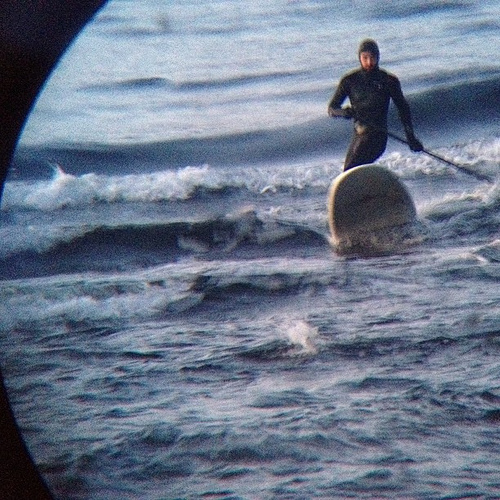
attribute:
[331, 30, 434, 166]
wet suit — black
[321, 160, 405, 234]
board — white, whtie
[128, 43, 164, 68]
water — blue, white, choppy, drk